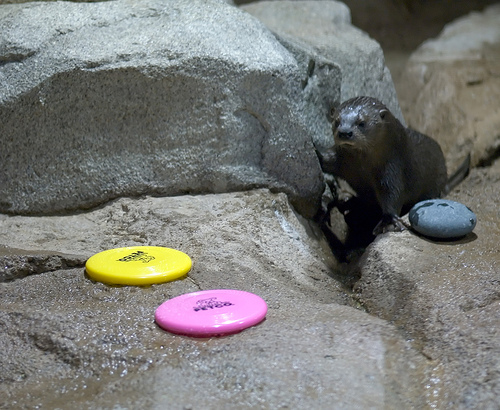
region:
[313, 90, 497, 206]
the otter is black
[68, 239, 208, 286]
the frisbee is yellow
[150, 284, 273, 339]
the frisbee is purple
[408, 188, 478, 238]
the rock is black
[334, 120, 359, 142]
the otter has a nose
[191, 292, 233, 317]
the words on the frisbee are black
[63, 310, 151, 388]
the stones are wet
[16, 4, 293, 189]
the stone is gray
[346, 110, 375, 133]
the otter has an eye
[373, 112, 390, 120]
the otter has an ear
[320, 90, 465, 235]
The seal is dark brown.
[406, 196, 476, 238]
The stone is gray.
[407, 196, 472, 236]
The stone is wet.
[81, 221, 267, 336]
Two frisbees are on the rock.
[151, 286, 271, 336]
The frisbee is pink.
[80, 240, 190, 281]
The frisbee is yellow.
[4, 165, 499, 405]
The rock has cracks in it.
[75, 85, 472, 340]
The seal is looking at the frisbees.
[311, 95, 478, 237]
The seal is wet.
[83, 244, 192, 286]
The frisbee is yellow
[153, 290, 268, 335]
The frisbee is circular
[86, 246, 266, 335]
Frisbees on the larger rocks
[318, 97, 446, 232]
An otter looking at the frisbees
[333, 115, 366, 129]
Eyes of the otter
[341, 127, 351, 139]
Nose of the otter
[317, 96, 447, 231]
The otter is wet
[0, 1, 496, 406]
Rocks around the otter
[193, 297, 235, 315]
A logo on the frisbee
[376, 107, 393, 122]
The ear of the otter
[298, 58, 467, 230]
animal between the rocks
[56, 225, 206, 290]
yellow frisbee on the rocks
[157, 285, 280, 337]
pink frisbee on the rocks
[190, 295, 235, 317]
graphics on the frisbee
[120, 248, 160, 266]
graphic on the frisbee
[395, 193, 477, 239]
stone on the rock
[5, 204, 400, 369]
rock with frisbees on it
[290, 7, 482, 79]
rocks behind the animal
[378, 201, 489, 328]
rock with stone on it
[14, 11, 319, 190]
rock next to animal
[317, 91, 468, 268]
a seal between the rocks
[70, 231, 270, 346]
pink and yellow frisbees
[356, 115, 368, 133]
the eye of a seal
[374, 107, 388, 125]
the ear of a seal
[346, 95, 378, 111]
fur on a seal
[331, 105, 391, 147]
a seal's head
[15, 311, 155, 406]
a rock that is wet with water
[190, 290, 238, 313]
a company logo and name on a frisbee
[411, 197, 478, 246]
a circular stone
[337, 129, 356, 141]
the nose of a seal